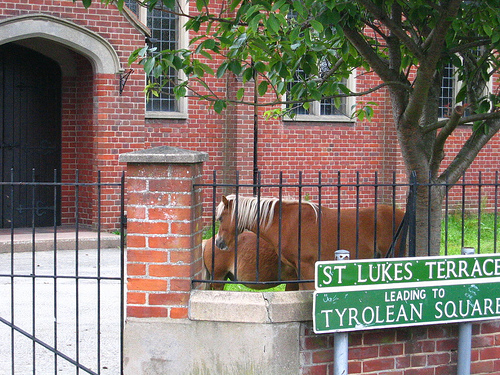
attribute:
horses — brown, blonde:
[169, 166, 381, 281]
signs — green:
[311, 260, 498, 337]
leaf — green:
[213, 99, 227, 114]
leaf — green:
[234, 85, 247, 99]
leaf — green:
[257, 78, 269, 97]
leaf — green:
[216, 60, 230, 80]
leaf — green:
[229, 59, 241, 76]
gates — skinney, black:
[9, 160, 129, 372]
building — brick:
[0, 1, 498, 231]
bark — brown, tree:
[392, 115, 444, 259]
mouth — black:
[212, 234, 232, 252]